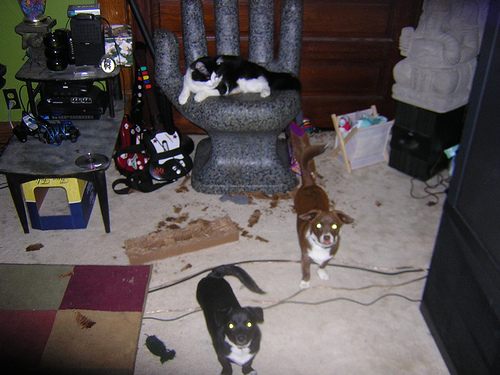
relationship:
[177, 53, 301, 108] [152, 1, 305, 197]
cat on hand chair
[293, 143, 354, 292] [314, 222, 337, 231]
dog has glowing eyes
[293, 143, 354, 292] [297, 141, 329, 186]
dog has tail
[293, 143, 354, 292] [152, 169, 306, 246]
dog near destroyed area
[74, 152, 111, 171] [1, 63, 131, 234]
disc on table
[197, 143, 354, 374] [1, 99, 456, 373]
dogs on floor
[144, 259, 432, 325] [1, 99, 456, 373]
wires on floor